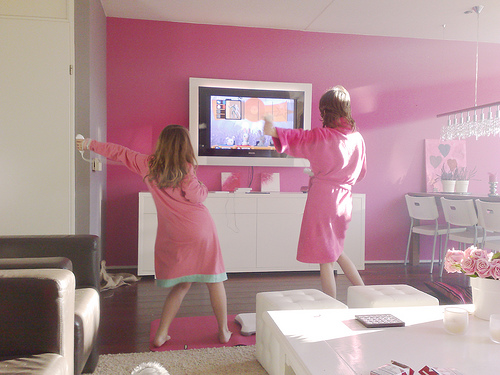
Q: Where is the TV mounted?
A: The wall.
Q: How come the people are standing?
A: Playing a video game.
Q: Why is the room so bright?
A: Sun shining in.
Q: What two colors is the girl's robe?
A: Pink, green.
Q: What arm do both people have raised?
A: Left.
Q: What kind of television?
A: Flat screen.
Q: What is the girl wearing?
A: Pink robe.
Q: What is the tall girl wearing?
A: Robe.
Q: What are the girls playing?
A: Video game.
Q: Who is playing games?
A: Two girls.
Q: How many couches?
A: Two.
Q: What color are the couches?
A: Brown.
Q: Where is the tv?
A: Wall.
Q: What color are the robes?
A: Pink.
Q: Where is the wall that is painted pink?
A: Behind tv.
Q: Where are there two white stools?
A: Behind woman.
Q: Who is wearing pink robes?
A: Two woman.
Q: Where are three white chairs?
A: Right of girls.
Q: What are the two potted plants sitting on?
A: Counter.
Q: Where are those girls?
A: At the living room.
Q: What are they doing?
A: Using a game controller stick.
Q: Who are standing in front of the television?
A: Two young sisters.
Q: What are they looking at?
A: At the television.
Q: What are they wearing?
A: Pink robes.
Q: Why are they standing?
A: To interact with the console.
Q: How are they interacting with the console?
A: By moving their bodies and the controller sticks.